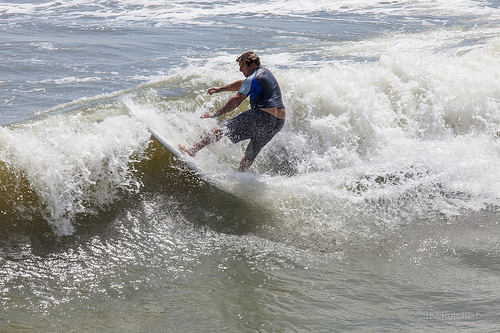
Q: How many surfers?
A: 1.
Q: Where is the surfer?
A: In the ocean.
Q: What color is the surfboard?
A: White.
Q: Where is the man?
A: In the water.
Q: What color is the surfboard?
A: White.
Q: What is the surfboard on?
A: A wave.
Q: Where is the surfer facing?
A: Into the wave.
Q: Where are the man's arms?
A: Extended in front of the body.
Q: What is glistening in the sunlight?
A: The water.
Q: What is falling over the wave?
A: White water.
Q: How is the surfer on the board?
A: Curved forward on the back.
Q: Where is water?
A: Wave.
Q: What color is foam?
A: White.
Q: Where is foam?
A: Ocean.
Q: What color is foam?
A: White.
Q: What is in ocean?
A: Foam.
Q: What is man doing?
A: Surfing.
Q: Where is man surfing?
A: Ocean.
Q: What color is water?
A: Blue.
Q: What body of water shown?
A: Ocean.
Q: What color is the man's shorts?
A: Blue.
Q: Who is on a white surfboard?
A: A man.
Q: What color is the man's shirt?
A: Blue.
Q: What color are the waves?
A: White.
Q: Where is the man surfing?
A: Ocean.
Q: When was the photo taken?
A: During the day.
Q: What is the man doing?
A: Surfing.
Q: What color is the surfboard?
A: White.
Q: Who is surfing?
A: A man.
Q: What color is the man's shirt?
A: Blue.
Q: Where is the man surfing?
A: In the ocean.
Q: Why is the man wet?
A: The man is surfing.